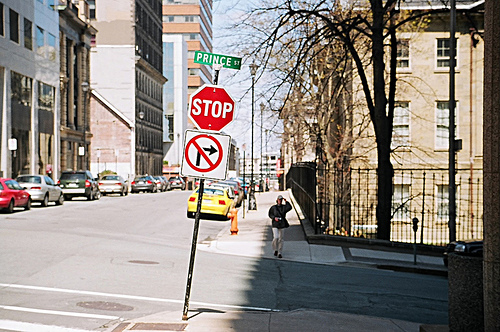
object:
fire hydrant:
[224, 205, 242, 236]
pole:
[248, 65, 257, 210]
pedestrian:
[267, 194, 294, 259]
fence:
[276, 159, 318, 230]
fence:
[316, 165, 482, 246]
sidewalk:
[292, 236, 447, 268]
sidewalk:
[213, 180, 312, 260]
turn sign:
[178, 132, 227, 174]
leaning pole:
[176, 67, 222, 320]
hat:
[277, 194, 285, 200]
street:
[0, 190, 497, 331]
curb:
[294, 239, 445, 274]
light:
[247, 61, 261, 80]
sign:
[185, 83, 238, 133]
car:
[185, 185, 235, 222]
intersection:
[0, 220, 191, 305]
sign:
[190, 48, 245, 70]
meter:
[411, 216, 421, 265]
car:
[0, 175, 35, 213]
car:
[12, 172, 67, 209]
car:
[59, 169, 103, 201]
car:
[95, 172, 129, 197]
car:
[129, 173, 160, 195]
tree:
[400, 0, 478, 235]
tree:
[217, 0, 406, 244]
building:
[305, 0, 496, 246]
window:
[432, 36, 463, 73]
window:
[382, 36, 415, 72]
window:
[430, 97, 463, 156]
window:
[376, 98, 415, 156]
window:
[431, 181, 460, 223]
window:
[389, 183, 414, 223]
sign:
[176, 127, 235, 182]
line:
[0, 279, 281, 314]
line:
[0, 300, 124, 322]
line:
[0, 316, 92, 332]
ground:
[0, 163, 495, 330]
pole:
[178, 69, 225, 321]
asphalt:
[0, 182, 489, 332]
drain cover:
[126, 258, 162, 265]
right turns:
[193, 144, 218, 166]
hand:
[282, 197, 288, 202]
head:
[275, 195, 285, 205]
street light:
[245, 57, 262, 211]